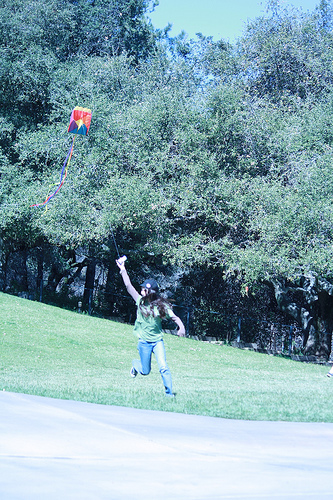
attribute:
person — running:
[115, 279, 185, 390]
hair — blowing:
[141, 293, 166, 308]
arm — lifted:
[95, 256, 150, 302]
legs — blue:
[115, 336, 184, 387]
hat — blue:
[145, 272, 167, 297]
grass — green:
[12, 319, 80, 364]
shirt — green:
[133, 306, 169, 343]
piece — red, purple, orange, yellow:
[64, 105, 109, 182]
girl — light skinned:
[122, 273, 182, 354]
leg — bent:
[149, 348, 179, 390]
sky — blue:
[179, 14, 228, 42]